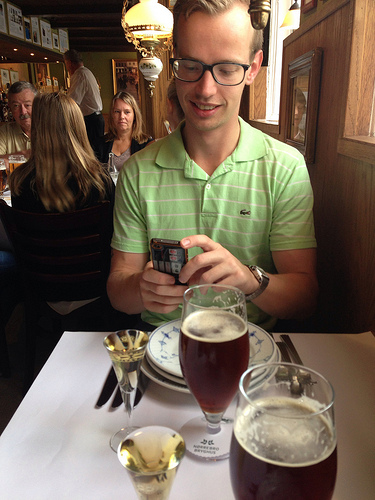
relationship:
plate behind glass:
[137, 319, 283, 396] [2, 152, 30, 198]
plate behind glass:
[146, 311, 277, 386] [2, 152, 30, 198]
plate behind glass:
[146, 309, 280, 378] [2, 152, 30, 198]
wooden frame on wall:
[278, 45, 325, 166] [282, 0, 373, 332]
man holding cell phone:
[107, 1, 318, 335] [149, 238, 188, 284]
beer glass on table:
[172, 283, 249, 464] [0, 330, 373, 499]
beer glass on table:
[229, 362, 337, 499] [0, 330, 373, 499]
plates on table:
[138, 315, 286, 396] [0, 330, 373, 499]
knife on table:
[95, 360, 122, 409] [0, 330, 373, 499]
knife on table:
[109, 386, 122, 409] [0, 330, 373, 499]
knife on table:
[131, 372, 149, 407] [0, 330, 373, 499]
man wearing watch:
[107, 1, 318, 335] [246, 263, 270, 301]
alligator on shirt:
[240, 208, 251, 214] [110, 115, 316, 327]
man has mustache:
[5, 69, 34, 155] [17, 110, 29, 119]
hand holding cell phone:
[138, 258, 195, 315] [148, 236, 190, 286]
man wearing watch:
[107, 1, 318, 335] [247, 258, 271, 300]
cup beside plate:
[100, 330, 145, 413] [144, 312, 283, 393]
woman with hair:
[6, 88, 141, 331] [6, 89, 113, 214]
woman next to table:
[6, 88, 141, 331] [14, 315, 371, 497]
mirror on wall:
[284, 71, 309, 143] [317, 11, 356, 171]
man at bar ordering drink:
[64, 49, 107, 120] [61, 48, 107, 161]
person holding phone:
[106, 0, 319, 350] [141, 235, 192, 294]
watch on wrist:
[250, 268, 267, 304] [244, 254, 278, 311]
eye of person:
[178, 58, 200, 81] [122, 12, 316, 349]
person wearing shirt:
[91, 11, 355, 349] [114, 126, 318, 253]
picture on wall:
[280, 48, 322, 161] [272, 1, 373, 334]